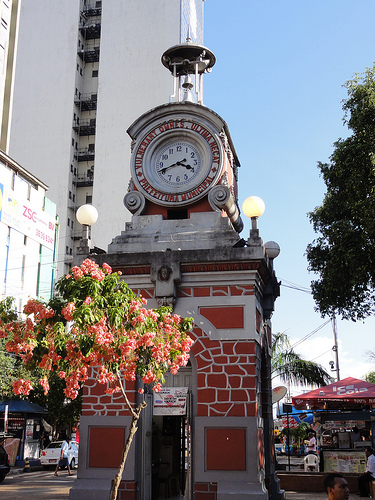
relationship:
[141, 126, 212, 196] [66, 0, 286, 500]
clock on brick tower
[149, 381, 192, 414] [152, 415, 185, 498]
banner above door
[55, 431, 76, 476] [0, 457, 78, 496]
man walking on street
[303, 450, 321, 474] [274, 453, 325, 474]
chair on sidewalk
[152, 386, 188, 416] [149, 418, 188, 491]
poster above door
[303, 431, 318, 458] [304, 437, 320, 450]
person wearing shirt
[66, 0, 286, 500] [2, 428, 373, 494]
brick tower on street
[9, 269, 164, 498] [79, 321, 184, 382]
tree with blossoms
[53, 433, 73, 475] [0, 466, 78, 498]
woman crossing street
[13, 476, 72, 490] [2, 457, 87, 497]
lines in road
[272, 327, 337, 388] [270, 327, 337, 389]
frond of tree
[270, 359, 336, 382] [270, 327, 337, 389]
frond of tree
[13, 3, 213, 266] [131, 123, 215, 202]
building behind clock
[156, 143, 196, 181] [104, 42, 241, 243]
clock face of tower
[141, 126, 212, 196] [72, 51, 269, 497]
clock on tower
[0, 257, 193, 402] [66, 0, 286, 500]
blossoms next to brick tower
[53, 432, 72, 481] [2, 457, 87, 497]
man crossing road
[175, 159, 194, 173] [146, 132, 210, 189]
hand of clock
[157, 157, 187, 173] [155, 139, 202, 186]
hands of clock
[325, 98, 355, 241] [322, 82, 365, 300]
leaves of a tree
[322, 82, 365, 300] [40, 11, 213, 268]
tree near tower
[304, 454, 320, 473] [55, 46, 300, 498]
chair near tower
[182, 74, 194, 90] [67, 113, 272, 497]
bell on top of tower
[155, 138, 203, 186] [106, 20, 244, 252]
clock face on clock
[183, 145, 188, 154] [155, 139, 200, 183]
number on clock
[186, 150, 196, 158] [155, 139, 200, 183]
number on clock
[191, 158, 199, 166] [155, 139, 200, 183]
number on clock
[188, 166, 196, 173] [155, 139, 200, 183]
number on clock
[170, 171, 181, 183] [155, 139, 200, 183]
number on clock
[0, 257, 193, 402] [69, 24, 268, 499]
blossoms in front of monument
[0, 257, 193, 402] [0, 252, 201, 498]
blossoms on tree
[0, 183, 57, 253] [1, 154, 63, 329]
billboard on building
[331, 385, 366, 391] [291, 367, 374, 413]
ice cola written on tent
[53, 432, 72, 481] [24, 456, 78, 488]
man walking across road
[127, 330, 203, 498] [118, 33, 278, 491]
door to tower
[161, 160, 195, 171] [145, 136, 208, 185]
hands are in clock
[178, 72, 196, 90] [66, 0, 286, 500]
bell on top of brick tower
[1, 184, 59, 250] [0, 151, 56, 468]
billboard on building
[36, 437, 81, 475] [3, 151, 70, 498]
car near building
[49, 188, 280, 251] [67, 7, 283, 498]
lights on monument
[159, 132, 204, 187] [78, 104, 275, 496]
clock on building